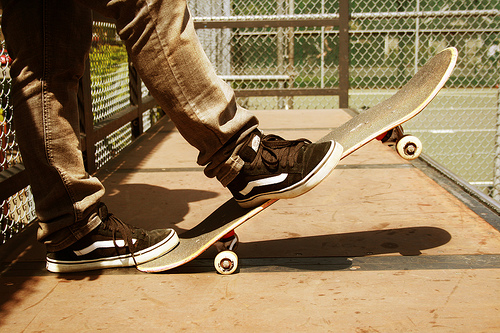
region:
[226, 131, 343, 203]
black and white sneaker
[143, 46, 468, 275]
grey and white skateboard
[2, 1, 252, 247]
mans grey denim jeans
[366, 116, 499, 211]
metal skate board ramp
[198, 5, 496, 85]
grey metal chain link fence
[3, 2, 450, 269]
man standing on skate board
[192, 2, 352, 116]
brown wood fence posts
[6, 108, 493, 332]
brown wood skate board platform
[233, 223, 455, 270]
shadow made by skateboard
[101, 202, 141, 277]
brown shoe laces on sneaker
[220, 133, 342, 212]
a black and white skate shoe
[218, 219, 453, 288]
the shadow of a skateboard on the concrete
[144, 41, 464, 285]
a black and white skateboard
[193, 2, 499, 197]
a chain link fence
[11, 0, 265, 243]
a pair of grey jeans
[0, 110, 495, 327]
concrete at the top of a half pipe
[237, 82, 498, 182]
a tennis court on the other side of the fence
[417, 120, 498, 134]
a white line on a tennis court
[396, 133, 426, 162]
a white wheel on a skateboard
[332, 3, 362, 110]
a dark grey metal support post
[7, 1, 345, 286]
legs of a person on a skateboard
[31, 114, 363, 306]
shoes are black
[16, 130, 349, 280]
shoes have white soles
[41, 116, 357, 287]
shoes has balck pins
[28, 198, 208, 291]
left leg pressing the board of a skateboard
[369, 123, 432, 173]
wheels in front of skateboard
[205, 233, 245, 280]
back wheels on back of skateboard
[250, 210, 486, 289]
shadow of skateboard projected on ground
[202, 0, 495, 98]
fence of metal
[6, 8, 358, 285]
person wears blue jeans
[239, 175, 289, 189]
a white stripe on a shoe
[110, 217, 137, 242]
black shoe laces on a shoe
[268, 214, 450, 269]
a shadow on the ground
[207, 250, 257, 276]
white wheels on the skateboard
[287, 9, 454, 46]
a metal chain link fence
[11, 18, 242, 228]
gray jeans on legs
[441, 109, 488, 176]
a green tennis court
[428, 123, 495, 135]
white lines on the court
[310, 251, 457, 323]
small stains on the sidewalk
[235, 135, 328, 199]
a black shoe covering a foot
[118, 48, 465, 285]
skateboard being tipped up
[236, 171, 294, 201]
white stripe on tennis shoe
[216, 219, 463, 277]
shadow of skateboard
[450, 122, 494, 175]
wire fence in background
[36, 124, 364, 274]
two feet holding skateboard up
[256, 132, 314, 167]
black shoe strings on tennis shoes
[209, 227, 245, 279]
red details on skateboard tires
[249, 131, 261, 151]
small white tag on tennis shoe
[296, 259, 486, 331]
tan cement under skateboard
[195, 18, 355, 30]
metal bar along fence